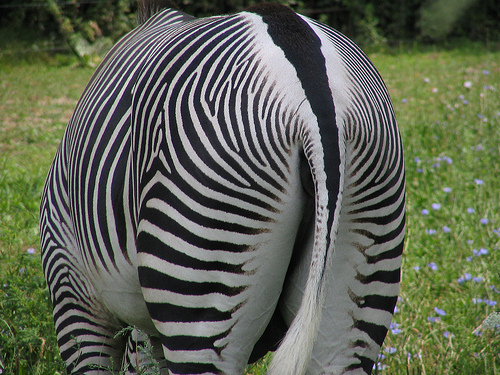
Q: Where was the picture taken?
A: It was taken at the garden.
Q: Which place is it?
A: It is a garden.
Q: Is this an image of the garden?
A: Yes, it is showing the garden.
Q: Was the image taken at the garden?
A: Yes, it was taken in the garden.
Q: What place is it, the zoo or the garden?
A: It is the garden.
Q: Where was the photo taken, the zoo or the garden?
A: It was taken at the garden.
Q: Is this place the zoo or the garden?
A: It is the garden.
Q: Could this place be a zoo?
A: No, it is a garden.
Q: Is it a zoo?
A: No, it is a garden.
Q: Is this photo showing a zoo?
A: No, the picture is showing a garden.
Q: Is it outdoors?
A: Yes, it is outdoors.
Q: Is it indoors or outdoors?
A: It is outdoors.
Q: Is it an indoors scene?
A: No, it is outdoors.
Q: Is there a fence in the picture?
A: No, there are no fences.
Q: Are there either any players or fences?
A: No, there are no fences or players.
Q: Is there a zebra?
A: Yes, there is a zebra.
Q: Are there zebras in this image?
A: Yes, there is a zebra.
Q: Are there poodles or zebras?
A: Yes, there is a zebra.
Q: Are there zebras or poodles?
A: Yes, there is a zebra.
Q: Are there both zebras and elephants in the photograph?
A: No, there is a zebra but no elephants.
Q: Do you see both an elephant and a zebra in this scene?
A: No, there is a zebra but no elephants.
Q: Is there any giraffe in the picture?
A: No, there are no giraffes.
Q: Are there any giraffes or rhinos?
A: No, there are no giraffes or rhinos.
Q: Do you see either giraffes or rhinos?
A: No, there are no giraffes or rhinos.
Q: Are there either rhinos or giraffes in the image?
A: No, there are no giraffes or rhinos.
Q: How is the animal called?
A: The animal is a zebra.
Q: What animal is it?
A: The animal is a zebra.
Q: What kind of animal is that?
A: This is a zebra.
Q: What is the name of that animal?
A: This is a zebra.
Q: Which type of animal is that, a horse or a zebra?
A: This is a zebra.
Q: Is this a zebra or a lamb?
A: This is a zebra.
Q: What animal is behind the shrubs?
A: The animal is a zebra.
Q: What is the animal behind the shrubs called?
A: The animal is a zebra.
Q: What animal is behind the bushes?
A: The animal is a zebra.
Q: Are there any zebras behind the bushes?
A: Yes, there is a zebra behind the bushes.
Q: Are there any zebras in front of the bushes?
A: No, the zebra is behind the bushes.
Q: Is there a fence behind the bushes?
A: No, there is a zebra behind the bushes.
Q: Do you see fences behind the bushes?
A: No, there is a zebra behind the bushes.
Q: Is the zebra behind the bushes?
A: Yes, the zebra is behind the bushes.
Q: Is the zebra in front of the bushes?
A: No, the zebra is behind the bushes.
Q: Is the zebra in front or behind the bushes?
A: The zebra is behind the bushes.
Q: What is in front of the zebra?
A: The bushes are in front of the zebra.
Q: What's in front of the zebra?
A: The bushes are in front of the zebra.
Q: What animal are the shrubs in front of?
A: The shrubs are in front of the zebra.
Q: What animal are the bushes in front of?
A: The shrubs are in front of the zebra.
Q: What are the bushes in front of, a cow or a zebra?
A: The bushes are in front of a zebra.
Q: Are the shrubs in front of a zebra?
A: Yes, the shrubs are in front of a zebra.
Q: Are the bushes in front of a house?
A: No, the bushes are in front of a zebra.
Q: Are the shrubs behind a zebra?
A: No, the shrubs are in front of a zebra.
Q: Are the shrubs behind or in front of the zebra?
A: The shrubs are in front of the zebra.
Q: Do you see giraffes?
A: No, there are no giraffes.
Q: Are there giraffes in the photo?
A: No, there are no giraffes.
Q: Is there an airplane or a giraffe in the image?
A: No, there are no giraffes or airplanes.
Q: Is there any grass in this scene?
A: Yes, there is grass.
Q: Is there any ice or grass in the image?
A: Yes, there is grass.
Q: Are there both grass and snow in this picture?
A: No, there is grass but no snow.